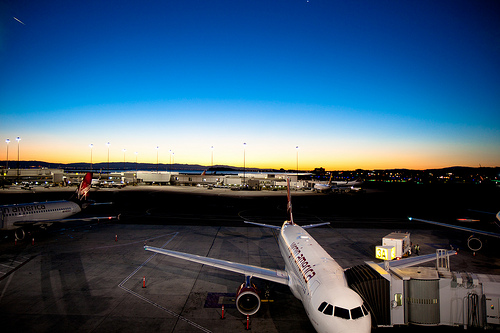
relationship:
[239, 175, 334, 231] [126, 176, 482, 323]
tail of a plane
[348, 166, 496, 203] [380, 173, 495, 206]
"a dark taxiway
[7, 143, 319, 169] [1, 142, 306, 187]
lights in distance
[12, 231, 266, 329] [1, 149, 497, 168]
cone on airway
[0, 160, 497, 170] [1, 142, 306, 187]
mountains in distance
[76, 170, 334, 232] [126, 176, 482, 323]
wing of a plane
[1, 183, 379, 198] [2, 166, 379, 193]
vehicle on ground"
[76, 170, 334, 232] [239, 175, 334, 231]
wing of a plane"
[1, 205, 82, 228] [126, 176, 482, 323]
windows on a plane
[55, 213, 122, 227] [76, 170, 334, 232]
red light on wing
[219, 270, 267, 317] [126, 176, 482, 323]
engine of plane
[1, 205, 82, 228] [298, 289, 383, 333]
windows of cockpit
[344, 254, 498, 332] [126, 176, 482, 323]
cart attached to plane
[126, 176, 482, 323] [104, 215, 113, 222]
plane with red light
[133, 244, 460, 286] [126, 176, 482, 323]
wings of plane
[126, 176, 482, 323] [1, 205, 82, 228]
plane has windows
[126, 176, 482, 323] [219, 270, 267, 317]
plane has engines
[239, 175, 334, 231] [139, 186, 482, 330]
tail of jet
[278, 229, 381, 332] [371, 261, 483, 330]
hood of jetway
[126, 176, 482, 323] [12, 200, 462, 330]
airplane on ground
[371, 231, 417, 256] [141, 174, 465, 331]
luggage loaded on plane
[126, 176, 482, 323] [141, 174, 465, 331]
engine on plane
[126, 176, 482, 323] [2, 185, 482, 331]
plane on ground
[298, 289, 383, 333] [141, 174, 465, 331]
cockpit window on plane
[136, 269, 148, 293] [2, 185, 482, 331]
cone on ground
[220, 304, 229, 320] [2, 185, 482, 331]
cone on ground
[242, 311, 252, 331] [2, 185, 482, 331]
cone on ground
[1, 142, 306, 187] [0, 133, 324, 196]
poles at airport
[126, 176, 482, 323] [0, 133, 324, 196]
plane parking in airport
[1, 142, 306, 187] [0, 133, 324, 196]
light poles in airport